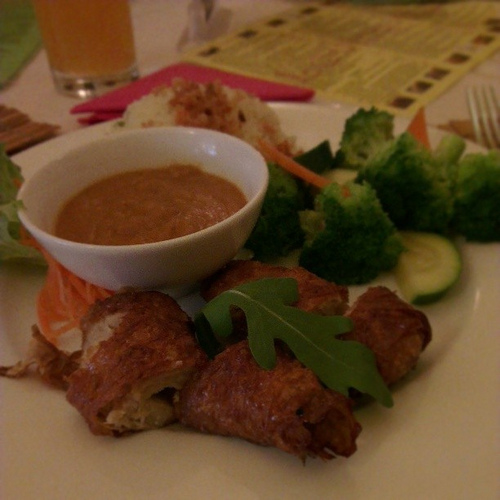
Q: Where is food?
A: On a plate.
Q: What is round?
A: A bowl.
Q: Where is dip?
A: In a bowl.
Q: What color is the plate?
A: White.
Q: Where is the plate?
A: On a table.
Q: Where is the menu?
A: Top right.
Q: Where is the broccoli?
A: On plate.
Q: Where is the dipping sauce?
A: In bowl.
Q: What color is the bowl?
A: White.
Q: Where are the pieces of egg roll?
A: On plate.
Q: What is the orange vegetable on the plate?
A: Carrot.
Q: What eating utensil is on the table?
A: Fork.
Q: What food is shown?
A: Broccoli, carrots,.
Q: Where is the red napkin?
A: Above the plate.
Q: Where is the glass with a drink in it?
A: At the top left side of the image.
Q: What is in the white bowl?
A: Sauce.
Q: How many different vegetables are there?
A: Three.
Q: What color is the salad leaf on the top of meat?
A: Green.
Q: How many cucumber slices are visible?
A: One.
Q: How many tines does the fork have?
A: Four.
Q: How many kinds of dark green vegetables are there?
A: Three.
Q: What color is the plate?
A: White.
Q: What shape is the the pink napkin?
A: Triangle.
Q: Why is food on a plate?
A: To be eaten.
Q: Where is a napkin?
A: On the table.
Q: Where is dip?
A: In a small bowl.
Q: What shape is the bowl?
A: Round.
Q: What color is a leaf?
A: Green.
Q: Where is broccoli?
A: On the plate.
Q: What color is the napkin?
A: Pink.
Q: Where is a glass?
A: On table.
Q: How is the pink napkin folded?
A: In a triangle.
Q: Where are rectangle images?
A: Along the edge.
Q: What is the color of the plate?
A: White.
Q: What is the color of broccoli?
A: Green.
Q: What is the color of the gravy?
A: Brown.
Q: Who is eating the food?
A: No one.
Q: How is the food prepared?
A: Fried.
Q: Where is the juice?
A: On the table.